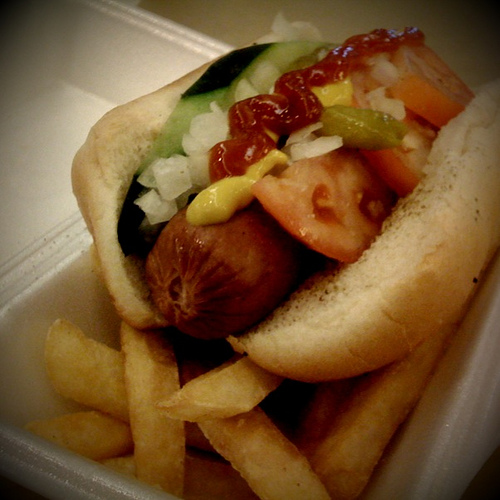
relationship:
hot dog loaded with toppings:
[54, 8, 496, 379] [115, 25, 475, 254]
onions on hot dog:
[128, 99, 230, 226] [137, 192, 300, 350]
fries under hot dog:
[45, 379, 402, 499] [154, 212, 282, 336]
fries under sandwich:
[45, 379, 402, 499] [74, 27, 491, 341]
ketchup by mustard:
[249, 44, 474, 264] [177, 145, 307, 248]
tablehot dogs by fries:
[69, 14, 499, 379] [24, 319, 460, 488]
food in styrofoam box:
[22, 26, 499, 498] [4, 23, 496, 498]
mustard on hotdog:
[178, 147, 293, 230] [67, 20, 498, 386]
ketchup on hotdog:
[206, 17, 429, 180] [67, 20, 498, 386]